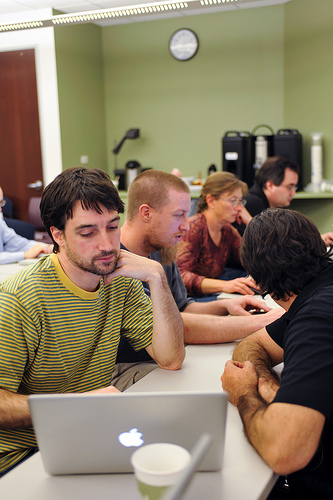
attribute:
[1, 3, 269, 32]
lighting — fluorescent, overhead 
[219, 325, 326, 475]
mans arms —  man's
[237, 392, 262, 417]
thick hair —  thick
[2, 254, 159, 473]
shirt —  yellow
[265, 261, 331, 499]
shirt — black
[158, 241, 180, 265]
beard — long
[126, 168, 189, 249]
head —  buzzed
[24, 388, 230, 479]
laptop —  mac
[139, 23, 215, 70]
clock — black and white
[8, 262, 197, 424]
shirt —  striped,  yellow and black, tee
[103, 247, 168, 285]
hand —  man's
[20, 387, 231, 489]
computer —  silver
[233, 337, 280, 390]
hair — black, thick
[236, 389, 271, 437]
hair — thick, black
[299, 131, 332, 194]
cups — in stack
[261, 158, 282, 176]
hair — black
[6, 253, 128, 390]
shirt —  yellow and blue,  striped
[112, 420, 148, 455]
logo —  apple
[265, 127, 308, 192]
coffee dispenser — commercial , thermal 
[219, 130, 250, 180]
coffee dispenser — thermal , commercial 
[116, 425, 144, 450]
logo —  lite up,  white,  apple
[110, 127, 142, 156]
projector —  for overhead 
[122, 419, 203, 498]
cup —  green and white,  styrofoam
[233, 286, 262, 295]
mouse —  black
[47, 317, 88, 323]
stripes —  blue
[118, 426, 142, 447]
label —  apple 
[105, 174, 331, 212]
counter — green